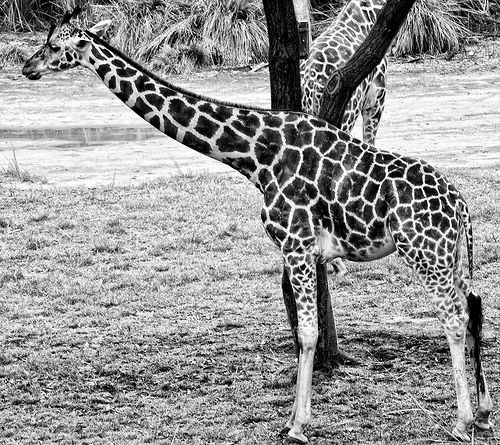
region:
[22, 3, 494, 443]
giraffe with long neck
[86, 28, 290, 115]
dark fur on mane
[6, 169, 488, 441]
grass below giraffe's feet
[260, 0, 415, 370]
thin dark tree trunk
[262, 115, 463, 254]
spots on giraffe's back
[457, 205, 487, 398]
dark hair on bottom of tail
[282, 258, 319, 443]
long leg with knobby knee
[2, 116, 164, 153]
puddle of murky water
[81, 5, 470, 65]
sprouts of grass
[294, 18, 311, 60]
back of sign posted on tree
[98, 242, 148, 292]
this is the ground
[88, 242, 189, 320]
the ground has grass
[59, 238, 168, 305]
the grass is short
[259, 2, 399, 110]
this is a tree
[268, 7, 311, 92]
the tree is short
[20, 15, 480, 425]
these are two giraffes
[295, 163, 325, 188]
the fur is well combed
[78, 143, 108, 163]
the area is arid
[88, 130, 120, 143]
the area is wet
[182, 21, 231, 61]
the leaves are big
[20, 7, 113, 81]
Head of a giraffe pointing left.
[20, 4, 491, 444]
Fully visible giraffe.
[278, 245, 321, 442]
Two front legs of a fully visible giraffe.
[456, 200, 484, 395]
Long black and white tail of a giraffe.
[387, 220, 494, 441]
Two back legs of a fully visible giraffe.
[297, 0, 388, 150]
A giraffe past the tree.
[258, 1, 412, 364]
A dark tree in between the giraffes.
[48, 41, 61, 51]
A dark eye of a fully visible giraffe.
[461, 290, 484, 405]
The black end of a fully visible giraffe.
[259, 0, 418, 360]
A very dark tree in the middle of the giraffes.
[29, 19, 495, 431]
large giraffe in front of a tree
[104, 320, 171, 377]
large patches of grass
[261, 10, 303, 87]
wood tree with wave bark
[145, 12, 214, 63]
large grass strubs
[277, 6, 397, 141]
giraffe behind a tree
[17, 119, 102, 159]
small pond of water with moss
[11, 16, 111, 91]
head of a giraffe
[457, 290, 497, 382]
black patches on leg of giraffe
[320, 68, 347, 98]
cut branch off tree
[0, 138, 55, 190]
grass growing from side of pond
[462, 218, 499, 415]
tail of the giraffe with fringes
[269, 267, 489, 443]
legs of the giraffe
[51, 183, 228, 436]
dirt with grass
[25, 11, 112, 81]
head of the giraffe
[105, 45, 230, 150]
neck of the giraffe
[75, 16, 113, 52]
ears of the giraffe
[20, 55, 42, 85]
nose and mouth of the giraffe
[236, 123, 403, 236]
brown and white color polygon shape of the skin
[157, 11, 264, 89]
plants with dirt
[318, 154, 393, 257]
stomach of the giraffe